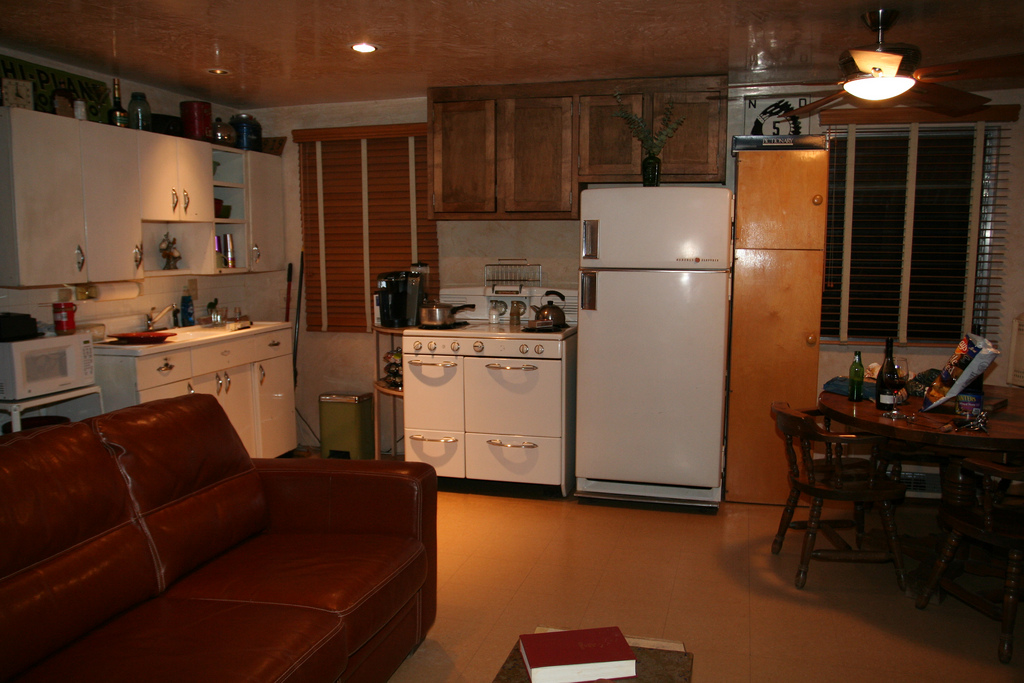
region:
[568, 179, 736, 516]
white fridge in a kitchen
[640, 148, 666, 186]
vase on a white fridge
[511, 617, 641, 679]
red book on a table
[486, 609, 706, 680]
coffee table in front of a couch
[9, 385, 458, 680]
red couch near a table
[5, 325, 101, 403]
white microwave under a cabinet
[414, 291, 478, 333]
pot on the stove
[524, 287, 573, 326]
kettle on the stove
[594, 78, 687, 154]
plant in the vase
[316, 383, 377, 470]
green colored trash bin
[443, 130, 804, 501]
fridge in the room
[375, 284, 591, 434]
stove next to the fridge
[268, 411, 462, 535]
arm of the couch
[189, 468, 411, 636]
cushion of the couch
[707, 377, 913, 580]
chair next to table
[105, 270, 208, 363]
sink on the counter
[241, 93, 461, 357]
blinds on the window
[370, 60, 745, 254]
cabinets above the fridge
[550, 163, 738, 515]
the refrigerator is white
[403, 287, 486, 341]
a pot on a stove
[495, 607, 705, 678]
the book is red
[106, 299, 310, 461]
the counter is white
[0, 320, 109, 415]
the microwave is white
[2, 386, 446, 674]
Shiny red leather couch.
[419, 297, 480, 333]
Aluminum pot sitting on oven burner.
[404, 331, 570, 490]
Controls and closed doors on oven.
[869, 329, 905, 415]
Wine bottle sitting on table.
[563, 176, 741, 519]
Freezer and refrigerator combination.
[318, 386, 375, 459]
Closed green waste bin.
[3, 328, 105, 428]
Microwave oven sitting on table.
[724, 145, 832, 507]
Two wooden storage cabinets.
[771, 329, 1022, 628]
Wooden dining room table and chairs.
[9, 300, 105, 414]
White microwave on a stand.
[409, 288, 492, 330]
Silver saucepan on the stove.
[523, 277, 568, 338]
Teakettle on the stove.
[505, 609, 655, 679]
Red book on the table.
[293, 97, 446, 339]
Wooden blinds in the window.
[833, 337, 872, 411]
Green bottle on the table.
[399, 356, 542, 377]
Silver handles on the stove.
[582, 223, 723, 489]
a fridge that is white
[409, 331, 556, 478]
an oven that is white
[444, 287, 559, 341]
a stove that is white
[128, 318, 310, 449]
a group of cabinets that is white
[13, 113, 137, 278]
a cabinet that is white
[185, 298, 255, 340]
a counter that is white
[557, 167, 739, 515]
white refrigerator in kitchen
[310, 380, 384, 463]
green metal trash can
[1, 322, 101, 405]
white microwave in kitchen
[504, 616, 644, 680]
red thick book on coffee table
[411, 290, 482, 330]
metal pot on top of stove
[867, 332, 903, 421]
wine bottle on top of circular wooden table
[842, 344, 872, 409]
green bottle on top of table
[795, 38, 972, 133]
light on the fan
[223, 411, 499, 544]
arm of the couch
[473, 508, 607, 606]
tile next to fridge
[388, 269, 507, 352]
pan on the stove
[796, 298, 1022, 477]
items on the table